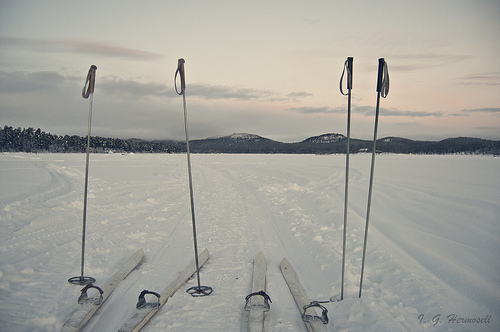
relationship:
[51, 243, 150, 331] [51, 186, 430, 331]
ski in snow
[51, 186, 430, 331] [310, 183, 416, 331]
snow with tracks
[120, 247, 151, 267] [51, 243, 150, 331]
tip of board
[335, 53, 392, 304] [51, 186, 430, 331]
poles in snow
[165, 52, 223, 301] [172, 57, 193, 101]
pole has holder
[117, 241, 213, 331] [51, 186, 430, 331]
ski in snow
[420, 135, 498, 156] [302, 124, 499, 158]
hills on horizon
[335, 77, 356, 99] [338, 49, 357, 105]
part of hooker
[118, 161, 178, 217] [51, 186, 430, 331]
part of snow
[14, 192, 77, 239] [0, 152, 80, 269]
part of line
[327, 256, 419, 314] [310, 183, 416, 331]
part of tracks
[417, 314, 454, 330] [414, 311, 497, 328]
part of writing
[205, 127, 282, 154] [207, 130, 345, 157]
part of mountain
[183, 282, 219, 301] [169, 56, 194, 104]
bottom of hooker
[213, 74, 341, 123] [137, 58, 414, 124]
part of sky